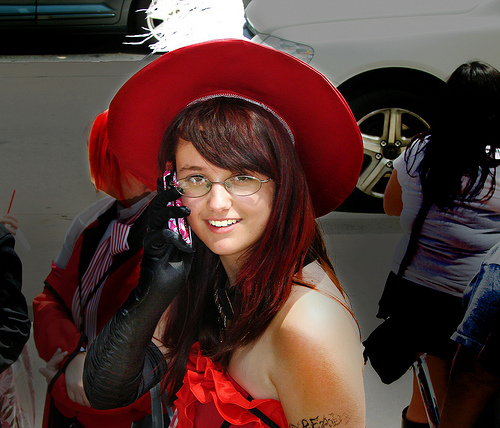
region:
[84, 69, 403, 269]
Red hat on a woman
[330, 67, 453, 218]
tire and wheel on a white car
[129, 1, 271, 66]
White feather on a red hat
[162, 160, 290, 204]
Wire frame glasses on a woman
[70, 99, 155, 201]
Red feather on a red hat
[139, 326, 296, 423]
Red ruffles on a dress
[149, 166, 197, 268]
Pink and white cell phone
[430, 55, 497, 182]
back of woman's head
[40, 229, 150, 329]
red and white striped shirt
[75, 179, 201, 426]
Elbow length black glove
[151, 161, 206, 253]
cellphone is pink and grey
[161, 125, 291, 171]
The girl has hair.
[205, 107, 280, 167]
The girl has red hair.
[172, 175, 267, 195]
The girl is wearing glasses.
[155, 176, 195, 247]
The girl is holding her phone up to her ear.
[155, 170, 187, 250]
The phone is pink and white.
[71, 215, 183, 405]
The girl is wearing a black glove.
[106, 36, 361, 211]
The girl is wearing a red hat.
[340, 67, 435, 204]
In the picture a tire is in the back.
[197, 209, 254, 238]
The girl is smiling.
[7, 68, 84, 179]
The wall is grey.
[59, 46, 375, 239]
A red hat on a girl's head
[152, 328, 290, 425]
The top of a red dress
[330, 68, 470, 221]
A car's left front tire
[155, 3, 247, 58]
A white feather on top of a hat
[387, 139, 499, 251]
A woman's white t-shirt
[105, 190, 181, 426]
A girl's black glove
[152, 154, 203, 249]
A pink and white cell phone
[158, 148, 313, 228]
A pair of glasses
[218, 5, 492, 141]
A white car.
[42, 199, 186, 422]
A red jacket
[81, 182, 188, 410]
woman's sleeve is black